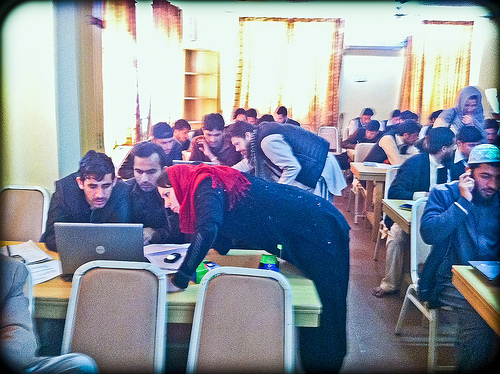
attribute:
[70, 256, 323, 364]
chairs — empty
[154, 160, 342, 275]
woman — over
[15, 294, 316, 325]
table — green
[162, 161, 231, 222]
scarf — red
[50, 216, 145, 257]
laptop — grey, silver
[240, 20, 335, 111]
curtains — yellow, big, gold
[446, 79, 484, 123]
scarf — grey, blue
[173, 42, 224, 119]
bookcase — brown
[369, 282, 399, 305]
foot — bare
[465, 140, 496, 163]
hat — green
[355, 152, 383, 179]
table — wooden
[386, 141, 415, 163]
arms — crossed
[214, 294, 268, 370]
seat — brown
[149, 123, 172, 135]
hat — black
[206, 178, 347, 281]
dress — black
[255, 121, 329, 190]
vest — black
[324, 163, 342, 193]
hijab — gray